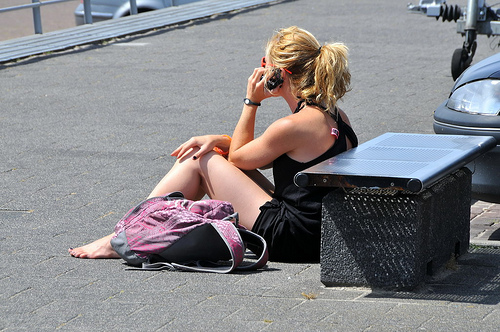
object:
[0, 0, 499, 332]
tile walkway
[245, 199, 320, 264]
shorts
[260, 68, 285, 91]
cell phone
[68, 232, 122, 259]
foot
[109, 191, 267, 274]
backpack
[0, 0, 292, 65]
bench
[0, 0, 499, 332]
ground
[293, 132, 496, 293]
bench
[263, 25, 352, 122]
hair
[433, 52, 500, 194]
car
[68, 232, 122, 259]
feet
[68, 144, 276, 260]
leg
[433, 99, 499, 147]
bumper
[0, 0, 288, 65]
guard rail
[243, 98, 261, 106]
bracelet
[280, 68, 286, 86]
ear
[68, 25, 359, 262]
woman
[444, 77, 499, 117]
headlight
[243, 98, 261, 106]
wristwatch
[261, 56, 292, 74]
sunglasses